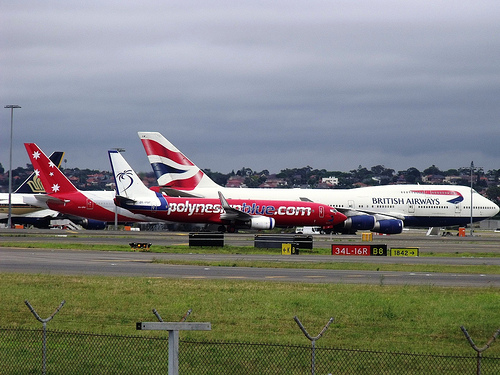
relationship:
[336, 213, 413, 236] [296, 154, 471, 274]
engine of plane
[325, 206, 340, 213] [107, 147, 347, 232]
cockpit of plane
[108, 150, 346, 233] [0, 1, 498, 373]
airplane at airport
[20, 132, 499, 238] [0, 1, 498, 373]
airliner at airport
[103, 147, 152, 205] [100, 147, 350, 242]
plane tail on plane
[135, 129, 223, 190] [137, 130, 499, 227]
tail on plane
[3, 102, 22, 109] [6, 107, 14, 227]
light on pole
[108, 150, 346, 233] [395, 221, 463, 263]
airplane on runway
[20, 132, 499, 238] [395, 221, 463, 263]
airliner on runway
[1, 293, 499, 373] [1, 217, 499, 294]
fence in front of runway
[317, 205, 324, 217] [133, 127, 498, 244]
door in front of airplane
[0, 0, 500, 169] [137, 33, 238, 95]
clouds are in sky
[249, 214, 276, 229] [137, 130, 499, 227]
engine on side of plane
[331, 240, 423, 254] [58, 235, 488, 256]
signs on fence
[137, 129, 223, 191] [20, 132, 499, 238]
tail of airliner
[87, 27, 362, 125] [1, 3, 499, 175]
clouds filling sky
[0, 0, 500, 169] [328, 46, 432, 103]
clouds in sky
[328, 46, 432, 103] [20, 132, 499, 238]
sky over airliner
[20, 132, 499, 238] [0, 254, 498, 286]
airliner on asphalt paves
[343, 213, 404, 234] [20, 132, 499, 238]
engine of airliner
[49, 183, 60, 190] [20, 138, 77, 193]
star on planes tail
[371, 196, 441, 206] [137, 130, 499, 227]
name on side of plane